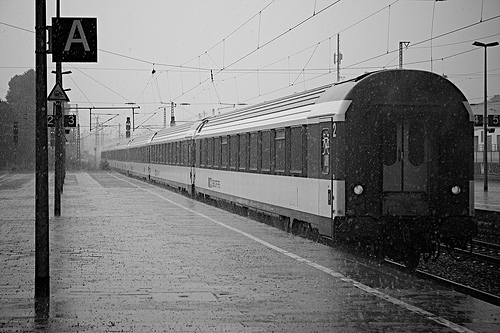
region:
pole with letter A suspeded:
[31, 0, 97, 326]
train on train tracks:
[105, 64, 480, 253]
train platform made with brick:
[6, 147, 466, 324]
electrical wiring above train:
[6, 1, 498, 158]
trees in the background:
[4, 65, 56, 175]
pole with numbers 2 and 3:
[41, 0, 87, 215]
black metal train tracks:
[411, 215, 498, 320]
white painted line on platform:
[104, 167, 494, 330]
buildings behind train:
[472, 87, 499, 186]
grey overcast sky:
[1, 0, 498, 151]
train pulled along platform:
[77, 46, 478, 292]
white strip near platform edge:
[110, 155, 455, 330]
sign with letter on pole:
[25, 7, 140, 309]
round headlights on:
[340, 170, 466, 210]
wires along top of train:
[135, 10, 436, 111]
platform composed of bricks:
[85, 205, 317, 320]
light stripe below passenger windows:
[110, 120, 356, 205]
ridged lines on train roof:
[176, 71, 346, 121]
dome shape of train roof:
[285, 60, 475, 125]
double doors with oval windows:
[365, 101, 445, 206]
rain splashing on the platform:
[132, 239, 284, 298]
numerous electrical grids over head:
[250, 11, 394, 62]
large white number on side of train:
[320, 105, 339, 155]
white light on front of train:
[346, 181, 397, 212]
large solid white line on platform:
[231, 226, 404, 311]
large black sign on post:
[41, 4, 115, 70]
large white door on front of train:
[373, 108, 442, 202]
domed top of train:
[325, 51, 497, 117]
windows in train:
[179, 116, 321, 170]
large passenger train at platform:
[103, 25, 486, 282]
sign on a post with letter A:
[29, 14, 131, 88]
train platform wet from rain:
[155, 216, 377, 318]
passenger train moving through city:
[144, 108, 465, 261]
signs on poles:
[39, 81, 79, 146]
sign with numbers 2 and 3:
[37, 113, 85, 138]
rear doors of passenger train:
[360, 98, 435, 238]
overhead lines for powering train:
[144, 53, 288, 126]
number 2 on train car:
[302, 110, 373, 167]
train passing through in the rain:
[95, 74, 475, 288]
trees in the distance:
[5, 63, 66, 162]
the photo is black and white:
[5, 4, 489, 328]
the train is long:
[92, 53, 485, 250]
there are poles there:
[25, 2, 85, 319]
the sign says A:
[30, 0, 127, 91]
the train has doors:
[375, 103, 450, 224]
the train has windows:
[195, 125, 322, 181]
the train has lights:
[337, 173, 475, 212]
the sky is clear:
[125, 13, 178, 42]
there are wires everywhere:
[153, 34, 363, 99]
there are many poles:
[22, 3, 105, 310]